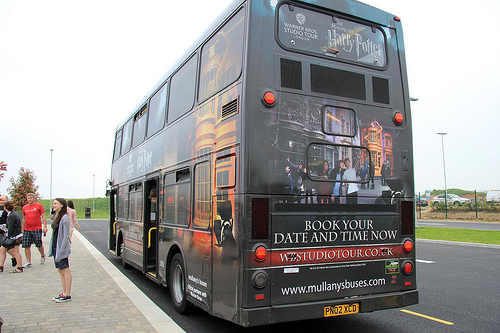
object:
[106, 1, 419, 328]
bus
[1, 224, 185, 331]
sidewalk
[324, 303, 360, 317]
license plate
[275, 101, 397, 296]
ad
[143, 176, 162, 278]
door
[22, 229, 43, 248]
shorts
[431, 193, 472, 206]
car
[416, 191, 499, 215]
parking lot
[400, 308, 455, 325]
line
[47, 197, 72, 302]
people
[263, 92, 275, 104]
light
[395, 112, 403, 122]
light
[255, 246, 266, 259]
light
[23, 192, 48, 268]
man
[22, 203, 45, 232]
red shirt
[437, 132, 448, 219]
street light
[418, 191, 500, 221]
fence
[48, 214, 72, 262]
sweater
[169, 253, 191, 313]
wheel